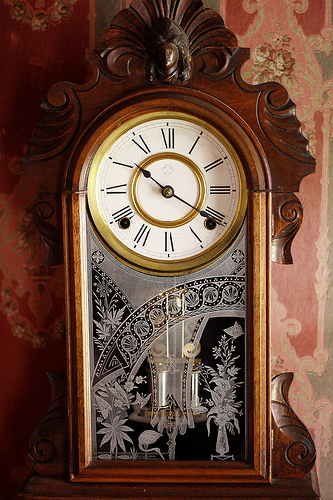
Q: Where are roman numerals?
A: On clock.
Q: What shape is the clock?
A: Round.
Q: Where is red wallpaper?
A: On the wall.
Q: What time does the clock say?
A: 10:21.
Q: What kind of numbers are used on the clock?
A: Roman numeral.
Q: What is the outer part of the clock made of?
A: Wood.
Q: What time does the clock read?
A: 10:20.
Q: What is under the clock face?
A: Etchings.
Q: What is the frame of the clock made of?
A: Wood.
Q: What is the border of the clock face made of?
A: Metal.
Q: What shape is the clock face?
A: Circle.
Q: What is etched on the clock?
A: The glass.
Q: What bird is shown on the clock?
A: A crane.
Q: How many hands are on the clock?
A: Two.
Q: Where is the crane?
A: Etched on the glass.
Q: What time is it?
A: 10:21.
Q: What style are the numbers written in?
A: Roman numerals.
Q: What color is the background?
A: Pink.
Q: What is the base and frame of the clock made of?
A: Wood.